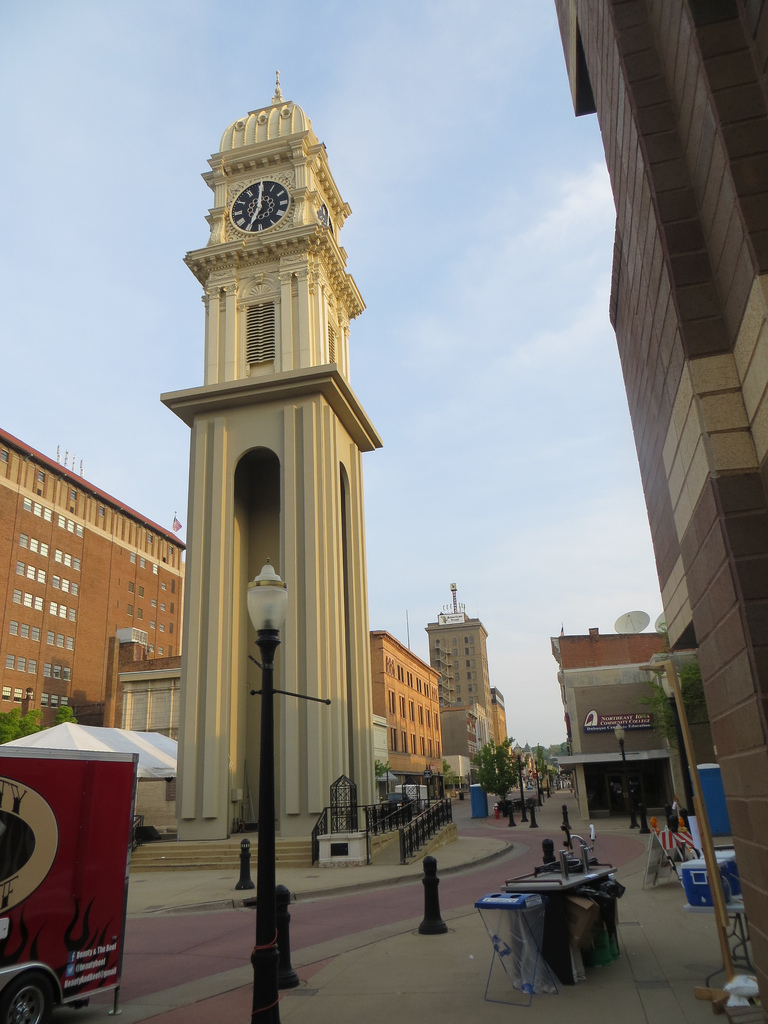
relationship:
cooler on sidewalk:
[660, 849, 759, 928] [654, 920, 709, 968]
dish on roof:
[601, 596, 673, 646] [559, 603, 653, 678]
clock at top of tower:
[230, 180, 291, 234] [200, 141, 363, 343]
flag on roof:
[160, 495, 187, 539] [108, 467, 161, 542]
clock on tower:
[216, 161, 305, 235] [125, 131, 447, 473]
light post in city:
[214, 749, 315, 978] [118, 471, 605, 903]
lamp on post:
[216, 559, 313, 660] [204, 649, 324, 943]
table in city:
[675, 889, 747, 942] [149, 523, 627, 927]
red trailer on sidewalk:
[0, 745, 139, 1022] [157, 985, 279, 1015]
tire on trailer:
[13, 976, 74, 1009] [3, 755, 100, 925]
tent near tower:
[38, 705, 162, 784] [167, 518, 391, 805]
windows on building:
[8, 494, 147, 630] [17, 536, 84, 632]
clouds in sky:
[502, 233, 577, 379] [478, 248, 556, 397]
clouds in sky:
[460, 237, 524, 372] [413, 227, 521, 435]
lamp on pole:
[246, 558, 290, 629] [206, 635, 300, 954]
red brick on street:
[162, 899, 224, 966] [119, 807, 648, 1016]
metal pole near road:
[419, 855, 449, 935] [97, 790, 610, 999]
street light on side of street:
[608, 710, 628, 747] [4, 808, 699, 1009]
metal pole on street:
[402, 829, 464, 957] [46, 769, 744, 974]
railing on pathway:
[384, 786, 469, 866] [217, 812, 623, 986]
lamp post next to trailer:
[229, 554, 296, 1021] [0, 719, 146, 1020]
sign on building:
[569, 698, 673, 752] [520, 599, 746, 882]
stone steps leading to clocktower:
[122, 833, 339, 874] [158, 37, 419, 858]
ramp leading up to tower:
[351, 773, 480, 866] [160, 69, 384, 839]